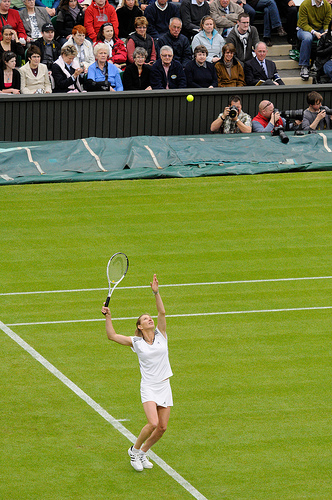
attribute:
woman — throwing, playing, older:
[96, 272, 190, 476]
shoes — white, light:
[124, 442, 158, 473]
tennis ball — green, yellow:
[183, 91, 196, 106]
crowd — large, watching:
[3, 0, 323, 94]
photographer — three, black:
[207, 94, 249, 137]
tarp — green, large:
[1, 129, 328, 183]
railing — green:
[3, 85, 331, 140]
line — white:
[194, 267, 331, 290]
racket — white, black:
[95, 250, 135, 310]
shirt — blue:
[86, 58, 124, 91]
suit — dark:
[247, 58, 281, 85]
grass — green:
[2, 179, 330, 499]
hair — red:
[72, 25, 88, 39]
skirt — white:
[138, 380, 176, 411]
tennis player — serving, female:
[125, 312, 176, 474]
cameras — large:
[215, 105, 306, 144]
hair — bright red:
[71, 25, 87, 40]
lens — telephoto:
[229, 111, 236, 117]